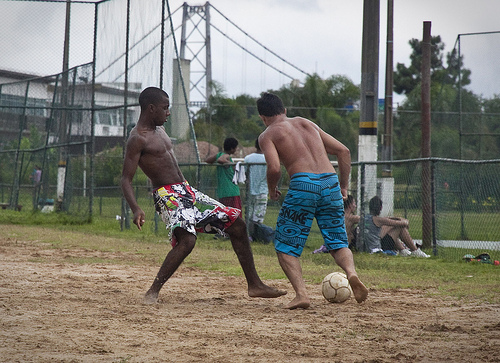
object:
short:
[272, 172, 347, 257]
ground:
[129, 312, 372, 361]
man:
[118, 85, 288, 305]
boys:
[122, 86, 370, 308]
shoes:
[394, 247, 434, 256]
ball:
[318, 269, 356, 302]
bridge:
[0, 6, 357, 115]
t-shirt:
[210, 150, 245, 198]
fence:
[2, 56, 113, 191]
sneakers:
[389, 246, 433, 260]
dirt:
[236, 306, 345, 340]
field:
[126, 269, 368, 342]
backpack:
[248, 216, 279, 244]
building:
[0, 63, 150, 164]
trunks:
[360, 216, 417, 256]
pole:
[420, 18, 435, 247]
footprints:
[273, 304, 321, 314]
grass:
[388, 261, 451, 285]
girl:
[29, 165, 45, 212]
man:
[257, 93, 368, 309]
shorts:
[149, 181, 243, 241]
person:
[343, 192, 433, 258]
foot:
[245, 283, 288, 297]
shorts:
[220, 194, 239, 212]